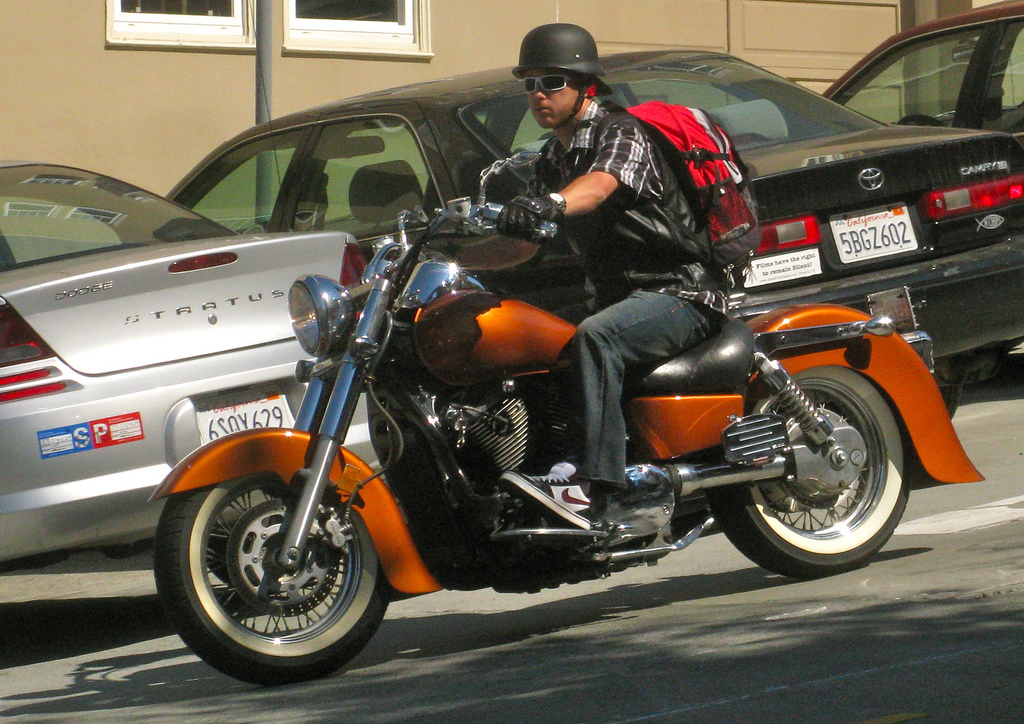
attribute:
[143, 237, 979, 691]
motorbike — orange, black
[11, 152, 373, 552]
car — parked , silver 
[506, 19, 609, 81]
helmet — black